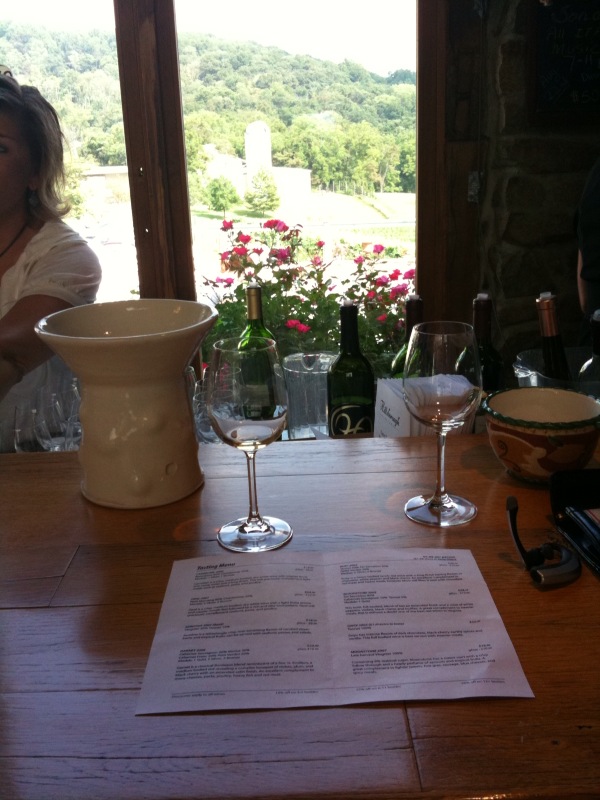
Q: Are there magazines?
A: No, there are no magazines.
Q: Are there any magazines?
A: No, there are no magazines.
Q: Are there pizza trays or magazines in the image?
A: No, there are no magazines or pizza trays.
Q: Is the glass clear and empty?
A: Yes, the glass is clear and empty.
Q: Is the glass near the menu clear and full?
A: No, the glass is clear but empty.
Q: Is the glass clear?
A: Yes, the glass is clear.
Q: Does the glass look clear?
A: Yes, the glass is clear.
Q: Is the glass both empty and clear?
A: Yes, the glass is empty and clear.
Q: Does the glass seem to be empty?
A: Yes, the glass is empty.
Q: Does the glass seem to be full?
A: No, the glass is empty.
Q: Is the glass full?
A: No, the glass is empty.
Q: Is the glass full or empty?
A: The glass is empty.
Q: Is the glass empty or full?
A: The glass is empty.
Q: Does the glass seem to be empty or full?
A: The glass is empty.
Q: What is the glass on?
A: The glass is on the table.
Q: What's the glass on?
A: The glass is on the table.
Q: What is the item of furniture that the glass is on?
A: The piece of furniture is a table.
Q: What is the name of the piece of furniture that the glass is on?
A: The piece of furniture is a table.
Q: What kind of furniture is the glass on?
A: The glass is on the table.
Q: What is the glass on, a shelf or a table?
A: The glass is on a table.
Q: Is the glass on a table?
A: Yes, the glass is on a table.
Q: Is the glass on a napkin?
A: No, the glass is on a table.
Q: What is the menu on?
A: The menu is on the table.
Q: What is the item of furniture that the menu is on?
A: The piece of furniture is a table.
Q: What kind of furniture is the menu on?
A: The menu is on the table.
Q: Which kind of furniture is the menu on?
A: The menu is on the table.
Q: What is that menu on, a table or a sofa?
A: The menu is on a table.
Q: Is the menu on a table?
A: Yes, the menu is on a table.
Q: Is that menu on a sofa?
A: No, the menu is on a table.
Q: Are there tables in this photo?
A: Yes, there is a table.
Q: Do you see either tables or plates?
A: Yes, there is a table.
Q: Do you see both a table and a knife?
A: No, there is a table but no knives.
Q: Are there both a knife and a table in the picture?
A: No, there is a table but no knives.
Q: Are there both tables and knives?
A: No, there is a table but no knives.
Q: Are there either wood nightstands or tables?
A: Yes, there is a wood table.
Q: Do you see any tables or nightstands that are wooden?
A: Yes, the table is wooden.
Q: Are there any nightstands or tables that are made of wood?
A: Yes, the table is made of wood.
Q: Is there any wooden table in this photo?
A: Yes, there is a wood table.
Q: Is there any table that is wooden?
A: Yes, there is a table that is wooden.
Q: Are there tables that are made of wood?
A: Yes, there is a table that is made of wood.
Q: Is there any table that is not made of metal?
A: Yes, there is a table that is made of wood.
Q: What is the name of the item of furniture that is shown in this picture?
A: The piece of furniture is a table.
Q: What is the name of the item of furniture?
A: The piece of furniture is a table.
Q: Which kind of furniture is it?
A: The piece of furniture is a table.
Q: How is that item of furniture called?
A: That is a table.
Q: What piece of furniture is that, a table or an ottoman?
A: That is a table.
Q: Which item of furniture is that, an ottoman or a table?
A: That is a table.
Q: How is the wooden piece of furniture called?
A: The piece of furniture is a table.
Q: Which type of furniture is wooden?
A: The furniture is a table.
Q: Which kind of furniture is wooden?
A: The furniture is a table.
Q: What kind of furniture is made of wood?
A: The furniture is a table.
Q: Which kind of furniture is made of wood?
A: The furniture is a table.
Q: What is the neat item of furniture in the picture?
A: The piece of furniture is a table.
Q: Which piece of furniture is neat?
A: The piece of furniture is a table.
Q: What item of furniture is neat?
A: The piece of furniture is a table.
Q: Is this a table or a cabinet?
A: This is a table.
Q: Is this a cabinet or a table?
A: This is a table.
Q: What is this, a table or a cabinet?
A: This is a table.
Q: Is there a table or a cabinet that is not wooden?
A: No, there is a table but it is wooden.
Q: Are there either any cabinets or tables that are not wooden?
A: No, there is a table but it is wooden.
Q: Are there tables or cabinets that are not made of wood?
A: No, there is a table but it is made of wood.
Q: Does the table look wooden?
A: Yes, the table is wooden.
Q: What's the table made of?
A: The table is made of wood.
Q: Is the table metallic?
A: No, the table is wooden.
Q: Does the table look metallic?
A: No, the table is wooden.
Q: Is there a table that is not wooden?
A: No, there is a table but it is wooden.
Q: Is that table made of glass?
A: No, the table is made of wood.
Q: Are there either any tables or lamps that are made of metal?
A: No, there is a table but it is made of wood.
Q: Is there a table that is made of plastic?
A: No, there is a table but it is made of wood.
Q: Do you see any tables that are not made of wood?
A: No, there is a table but it is made of wood.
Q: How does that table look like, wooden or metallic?
A: The table is wooden.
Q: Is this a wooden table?
A: Yes, this is a wooden table.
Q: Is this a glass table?
A: No, this is a wooden table.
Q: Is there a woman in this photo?
A: Yes, there is a woman.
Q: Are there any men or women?
A: Yes, there is a woman.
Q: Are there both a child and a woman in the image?
A: No, there is a woman but no children.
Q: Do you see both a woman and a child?
A: No, there is a woman but no children.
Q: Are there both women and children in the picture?
A: No, there is a woman but no children.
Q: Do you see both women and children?
A: No, there is a woman but no children.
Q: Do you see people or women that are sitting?
A: Yes, the woman is sitting.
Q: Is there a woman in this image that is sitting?
A: Yes, there is a woman that is sitting.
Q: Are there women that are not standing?
A: Yes, there is a woman that is sitting.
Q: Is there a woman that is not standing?
A: Yes, there is a woman that is sitting.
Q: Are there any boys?
A: No, there are no boys.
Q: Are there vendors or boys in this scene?
A: No, there are no boys or vendors.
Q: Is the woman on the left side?
A: Yes, the woman is on the left of the image.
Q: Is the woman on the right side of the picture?
A: No, the woman is on the left of the image.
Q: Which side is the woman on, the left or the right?
A: The woman is on the left of the image.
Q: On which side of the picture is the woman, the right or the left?
A: The woman is on the left of the image.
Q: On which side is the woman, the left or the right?
A: The woman is on the left of the image.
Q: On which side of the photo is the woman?
A: The woman is on the left of the image.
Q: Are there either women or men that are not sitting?
A: No, there is a woman but she is sitting.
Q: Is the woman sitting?
A: Yes, the woman is sitting.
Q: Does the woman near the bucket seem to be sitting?
A: Yes, the woman is sitting.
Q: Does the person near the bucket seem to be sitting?
A: Yes, the woman is sitting.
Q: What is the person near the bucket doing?
A: The woman is sitting.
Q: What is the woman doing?
A: The woman is sitting.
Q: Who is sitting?
A: The woman is sitting.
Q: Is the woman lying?
A: No, the woman is sitting.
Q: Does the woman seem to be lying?
A: No, the woman is sitting.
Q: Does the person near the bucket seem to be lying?
A: No, the woman is sitting.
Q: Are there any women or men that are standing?
A: No, there is a woman but she is sitting.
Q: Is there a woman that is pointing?
A: No, there is a woman but she is sitting.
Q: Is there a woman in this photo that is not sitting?
A: No, there is a woman but she is sitting.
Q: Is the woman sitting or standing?
A: The woman is sitting.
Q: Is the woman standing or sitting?
A: The woman is sitting.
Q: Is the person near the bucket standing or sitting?
A: The woman is sitting.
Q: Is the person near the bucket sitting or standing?
A: The woman is sitting.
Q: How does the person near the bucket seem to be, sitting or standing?
A: The woman is sitting.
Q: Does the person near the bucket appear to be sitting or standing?
A: The woman is sitting.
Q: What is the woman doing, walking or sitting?
A: The woman is sitting.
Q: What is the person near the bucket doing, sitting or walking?
A: The woman is sitting.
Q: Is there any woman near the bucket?
A: Yes, there is a woman near the bucket.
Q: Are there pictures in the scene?
A: No, there are no pictures.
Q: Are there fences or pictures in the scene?
A: No, there are no pictures or fences.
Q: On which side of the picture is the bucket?
A: The bucket is on the left of the image.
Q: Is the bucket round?
A: Yes, the bucket is round.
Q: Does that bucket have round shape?
A: Yes, the bucket is round.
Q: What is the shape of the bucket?
A: The bucket is round.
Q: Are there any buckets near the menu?
A: Yes, there is a bucket near the menu.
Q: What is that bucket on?
A: The bucket is on the table.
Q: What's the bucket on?
A: The bucket is on the table.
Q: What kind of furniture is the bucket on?
A: The bucket is on the table.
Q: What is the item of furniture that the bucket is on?
A: The piece of furniture is a table.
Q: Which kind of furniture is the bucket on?
A: The bucket is on the table.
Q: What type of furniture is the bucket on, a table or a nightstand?
A: The bucket is on a table.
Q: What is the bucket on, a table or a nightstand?
A: The bucket is on a table.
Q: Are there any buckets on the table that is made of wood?
A: Yes, there is a bucket on the table.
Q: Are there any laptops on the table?
A: No, there is a bucket on the table.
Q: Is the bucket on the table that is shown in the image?
A: Yes, the bucket is on the table.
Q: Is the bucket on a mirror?
A: No, the bucket is on the table.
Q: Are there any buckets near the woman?
A: Yes, there is a bucket near the woman.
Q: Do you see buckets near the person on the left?
A: Yes, there is a bucket near the woman.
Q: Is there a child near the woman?
A: No, there is a bucket near the woman.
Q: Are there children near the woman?
A: No, there is a bucket near the woman.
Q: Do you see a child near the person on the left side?
A: No, there is a bucket near the woman.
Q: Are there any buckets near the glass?
A: Yes, there is a bucket near the glass.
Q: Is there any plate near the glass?
A: No, there is a bucket near the glass.